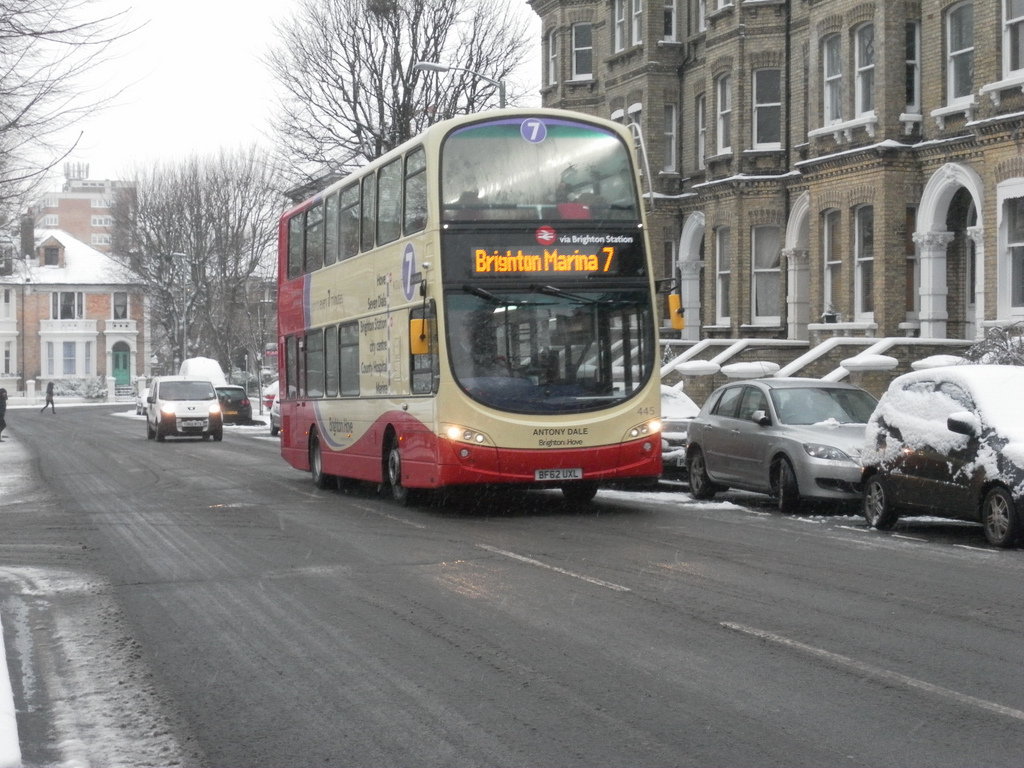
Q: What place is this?
A: It is a road.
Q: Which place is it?
A: It is a road.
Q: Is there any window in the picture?
A: Yes, there is a window.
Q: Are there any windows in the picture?
A: Yes, there is a window.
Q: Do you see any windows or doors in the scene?
A: Yes, there is a window.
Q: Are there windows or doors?
A: Yes, there is a window.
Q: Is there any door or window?
A: Yes, there is a window.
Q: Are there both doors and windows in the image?
A: Yes, there are both a window and a door.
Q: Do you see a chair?
A: No, there are no chairs.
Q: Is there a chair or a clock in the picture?
A: No, there are no chairs or clocks.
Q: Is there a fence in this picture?
A: No, there are no fences.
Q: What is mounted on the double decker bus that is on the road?
A: The sign is mounted on the bus.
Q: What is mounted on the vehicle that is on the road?
A: The sign is mounted on the bus.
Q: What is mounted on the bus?
A: The sign is mounted on the bus.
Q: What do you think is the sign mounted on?
A: The sign is mounted on the bus.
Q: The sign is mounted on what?
A: The sign is mounted on the bus.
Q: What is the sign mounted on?
A: The sign is mounted on the bus.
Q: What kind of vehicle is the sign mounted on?
A: The sign is mounted on the bus.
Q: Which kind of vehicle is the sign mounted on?
A: The sign is mounted on the bus.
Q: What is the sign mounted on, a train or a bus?
A: The sign is mounted on a bus.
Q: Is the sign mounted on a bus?
A: Yes, the sign is mounted on a bus.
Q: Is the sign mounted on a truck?
A: No, the sign is mounted on a bus.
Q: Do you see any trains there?
A: No, there are no trains.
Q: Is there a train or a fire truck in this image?
A: No, there are no trains or fire trucks.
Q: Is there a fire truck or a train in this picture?
A: No, there are no trains or fire trucks.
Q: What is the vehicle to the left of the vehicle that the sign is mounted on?
A: The vehicle is a car.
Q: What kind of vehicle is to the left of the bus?
A: The vehicle is a car.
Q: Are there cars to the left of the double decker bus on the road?
A: Yes, there is a car to the left of the bus.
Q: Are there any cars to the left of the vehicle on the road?
A: Yes, there is a car to the left of the bus.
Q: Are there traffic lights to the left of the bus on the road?
A: No, there is a car to the left of the bus.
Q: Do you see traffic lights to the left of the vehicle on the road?
A: No, there is a car to the left of the bus.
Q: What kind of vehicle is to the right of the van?
A: The vehicle is a car.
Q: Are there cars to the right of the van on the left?
A: Yes, there is a car to the right of the van.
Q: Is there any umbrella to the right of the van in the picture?
A: No, there is a car to the right of the van.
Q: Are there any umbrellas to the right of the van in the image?
A: No, there is a car to the right of the van.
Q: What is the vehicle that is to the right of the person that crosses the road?
A: The vehicle is a car.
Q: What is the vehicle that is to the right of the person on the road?
A: The vehicle is a car.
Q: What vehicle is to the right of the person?
A: The vehicle is a car.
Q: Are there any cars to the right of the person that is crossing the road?
A: Yes, there is a car to the right of the person.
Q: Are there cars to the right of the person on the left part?
A: Yes, there is a car to the right of the person.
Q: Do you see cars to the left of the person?
A: No, the car is to the right of the person.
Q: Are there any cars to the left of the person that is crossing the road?
A: No, the car is to the right of the person.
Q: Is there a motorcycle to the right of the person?
A: No, there is a car to the right of the person.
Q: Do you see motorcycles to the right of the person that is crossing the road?
A: No, there is a car to the right of the person.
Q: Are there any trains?
A: No, there are no trains.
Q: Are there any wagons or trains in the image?
A: No, there are no trains or wagons.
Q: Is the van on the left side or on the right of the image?
A: The van is on the left of the image.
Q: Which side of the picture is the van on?
A: The van is on the left of the image.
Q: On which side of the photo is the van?
A: The van is on the left of the image.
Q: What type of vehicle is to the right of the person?
A: The vehicle is a van.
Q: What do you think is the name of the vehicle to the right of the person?
A: The vehicle is a van.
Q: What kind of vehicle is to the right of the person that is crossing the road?
A: The vehicle is a van.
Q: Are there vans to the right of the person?
A: Yes, there is a van to the right of the person.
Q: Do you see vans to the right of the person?
A: Yes, there is a van to the right of the person.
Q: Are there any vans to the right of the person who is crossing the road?
A: Yes, there is a van to the right of the person.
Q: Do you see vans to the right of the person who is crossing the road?
A: Yes, there is a van to the right of the person.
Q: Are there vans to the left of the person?
A: No, the van is to the right of the person.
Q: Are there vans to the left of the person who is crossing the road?
A: No, the van is to the right of the person.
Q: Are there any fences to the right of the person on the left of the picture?
A: No, there is a van to the right of the person.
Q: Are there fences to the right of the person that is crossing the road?
A: No, there is a van to the right of the person.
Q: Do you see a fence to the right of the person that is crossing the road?
A: No, there is a van to the right of the person.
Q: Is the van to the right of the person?
A: Yes, the van is to the right of the person.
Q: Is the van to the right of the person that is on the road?
A: Yes, the van is to the right of the person.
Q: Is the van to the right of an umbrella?
A: No, the van is to the right of the person.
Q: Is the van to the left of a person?
A: No, the van is to the right of a person.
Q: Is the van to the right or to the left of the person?
A: The van is to the right of the person.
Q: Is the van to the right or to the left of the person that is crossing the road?
A: The van is to the right of the person.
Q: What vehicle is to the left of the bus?
A: The vehicle is a van.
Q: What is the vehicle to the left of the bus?
A: The vehicle is a van.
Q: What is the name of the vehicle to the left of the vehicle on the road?
A: The vehicle is a van.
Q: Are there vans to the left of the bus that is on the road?
A: Yes, there is a van to the left of the bus.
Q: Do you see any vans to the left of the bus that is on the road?
A: Yes, there is a van to the left of the bus.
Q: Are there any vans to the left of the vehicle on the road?
A: Yes, there is a van to the left of the bus.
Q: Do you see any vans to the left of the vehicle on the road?
A: Yes, there is a van to the left of the bus.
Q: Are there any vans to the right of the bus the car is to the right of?
A: No, the van is to the left of the bus.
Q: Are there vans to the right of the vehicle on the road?
A: No, the van is to the left of the bus.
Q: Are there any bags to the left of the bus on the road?
A: No, there is a van to the left of the bus.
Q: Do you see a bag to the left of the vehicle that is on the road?
A: No, there is a van to the left of the bus.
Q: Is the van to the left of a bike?
A: No, the van is to the left of a bus.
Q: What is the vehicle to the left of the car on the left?
A: The vehicle is a van.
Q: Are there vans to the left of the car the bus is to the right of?
A: Yes, there is a van to the left of the car.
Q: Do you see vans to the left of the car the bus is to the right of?
A: Yes, there is a van to the left of the car.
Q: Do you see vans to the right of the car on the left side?
A: No, the van is to the left of the car.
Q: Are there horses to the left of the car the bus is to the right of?
A: No, there is a van to the left of the car.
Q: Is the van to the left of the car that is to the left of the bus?
A: Yes, the van is to the left of the car.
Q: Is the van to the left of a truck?
A: No, the van is to the left of the car.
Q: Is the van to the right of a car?
A: No, the van is to the left of a car.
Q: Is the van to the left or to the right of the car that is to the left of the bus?
A: The van is to the left of the car.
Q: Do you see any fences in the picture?
A: No, there are no fences.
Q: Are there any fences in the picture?
A: No, there are no fences.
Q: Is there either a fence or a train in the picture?
A: No, there are no fences or trains.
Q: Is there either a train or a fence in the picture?
A: No, there are no fences or trains.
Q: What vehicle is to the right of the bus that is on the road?
A: The vehicle is a car.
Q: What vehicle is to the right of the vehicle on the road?
A: The vehicle is a car.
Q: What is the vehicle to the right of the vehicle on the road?
A: The vehicle is a car.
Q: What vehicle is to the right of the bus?
A: The vehicle is a car.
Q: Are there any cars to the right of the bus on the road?
A: Yes, there is a car to the right of the bus.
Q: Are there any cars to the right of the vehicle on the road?
A: Yes, there is a car to the right of the bus.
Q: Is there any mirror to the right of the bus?
A: No, there is a car to the right of the bus.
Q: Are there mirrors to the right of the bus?
A: No, there is a car to the right of the bus.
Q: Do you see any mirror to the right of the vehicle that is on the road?
A: No, there is a car to the right of the bus.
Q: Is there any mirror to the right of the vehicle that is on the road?
A: No, there is a car to the right of the bus.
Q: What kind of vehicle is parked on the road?
A: The vehicle is a car.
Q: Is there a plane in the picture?
A: No, there are no airplanes.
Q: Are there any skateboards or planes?
A: No, there are no planes or skateboards.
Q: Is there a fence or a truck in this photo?
A: No, there are no fences or trucks.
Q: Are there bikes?
A: No, there are no bikes.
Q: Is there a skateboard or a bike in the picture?
A: No, there are no bikes or skateboards.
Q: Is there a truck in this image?
A: No, there are no trucks.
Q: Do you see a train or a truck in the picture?
A: No, there are no trucks or trains.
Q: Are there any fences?
A: No, there are no fences.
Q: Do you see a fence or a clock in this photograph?
A: No, there are no fences or clocks.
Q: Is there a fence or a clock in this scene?
A: No, there are no fences or clocks.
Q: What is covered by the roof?
A: The building is covered by the roof.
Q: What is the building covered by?
A: The building is covered by the roof.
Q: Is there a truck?
A: No, there are no trucks.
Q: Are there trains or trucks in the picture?
A: No, there are no trucks or trains.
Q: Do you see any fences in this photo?
A: No, there are no fences.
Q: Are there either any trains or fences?
A: No, there are no fences or trains.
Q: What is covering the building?
A: The roof is covering the building.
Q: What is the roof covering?
A: The roof is covering the building.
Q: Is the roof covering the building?
A: Yes, the roof is covering the building.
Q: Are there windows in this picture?
A: Yes, there is a window.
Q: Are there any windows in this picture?
A: Yes, there is a window.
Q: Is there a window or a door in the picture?
A: Yes, there is a window.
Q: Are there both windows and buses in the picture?
A: Yes, there are both a window and a bus.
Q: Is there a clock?
A: No, there are no clocks.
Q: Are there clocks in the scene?
A: No, there are no clocks.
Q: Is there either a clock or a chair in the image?
A: No, there are no clocks or chairs.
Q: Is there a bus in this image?
A: Yes, there is a bus.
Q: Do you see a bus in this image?
A: Yes, there is a bus.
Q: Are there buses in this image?
A: Yes, there is a bus.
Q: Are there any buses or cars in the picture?
A: Yes, there is a bus.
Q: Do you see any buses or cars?
A: Yes, there is a bus.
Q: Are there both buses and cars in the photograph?
A: Yes, there are both a bus and a car.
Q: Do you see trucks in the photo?
A: No, there are no trucks.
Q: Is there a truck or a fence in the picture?
A: No, there are no trucks or fences.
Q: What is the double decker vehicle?
A: The vehicle is a bus.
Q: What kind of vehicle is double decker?
A: The vehicle is a bus.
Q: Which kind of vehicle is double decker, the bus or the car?
A: The bus is double decker.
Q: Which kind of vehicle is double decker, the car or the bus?
A: The bus is double decker.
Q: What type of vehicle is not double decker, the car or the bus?
A: The car is not double decker.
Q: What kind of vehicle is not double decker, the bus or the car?
A: The car is not double decker.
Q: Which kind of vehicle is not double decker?
A: The vehicle is a car.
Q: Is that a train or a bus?
A: That is a bus.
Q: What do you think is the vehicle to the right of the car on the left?
A: The vehicle is a bus.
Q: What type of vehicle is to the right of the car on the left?
A: The vehicle is a bus.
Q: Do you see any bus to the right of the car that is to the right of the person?
A: Yes, there is a bus to the right of the car.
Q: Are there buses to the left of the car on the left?
A: No, the bus is to the right of the car.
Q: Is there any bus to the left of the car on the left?
A: No, the bus is to the right of the car.